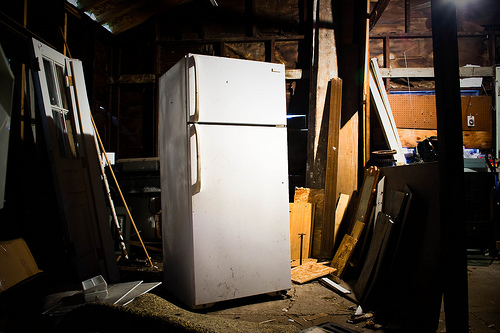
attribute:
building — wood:
[95, 13, 162, 169]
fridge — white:
[148, 40, 297, 309]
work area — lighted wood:
[290, 5, 499, 330]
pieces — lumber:
[297, 54, 389, 268]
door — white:
[30, 34, 133, 274]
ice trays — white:
[77, 268, 113, 306]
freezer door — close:
[184, 52, 287, 124]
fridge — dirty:
[154, 49, 295, 304]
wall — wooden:
[364, 3, 499, 71]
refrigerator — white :
[153, 39, 333, 322]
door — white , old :
[28, 24, 142, 265]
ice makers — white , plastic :
[70, 268, 115, 313]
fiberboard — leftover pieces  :
[275, 208, 382, 297]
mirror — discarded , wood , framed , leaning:
[333, 160, 385, 289]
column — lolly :
[421, 11, 471, 329]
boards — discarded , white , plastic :
[59, 266, 168, 320]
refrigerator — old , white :
[137, 37, 322, 331]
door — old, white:
[24, 36, 126, 273]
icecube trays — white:
[77, 273, 108, 292]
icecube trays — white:
[83, 291, 112, 302]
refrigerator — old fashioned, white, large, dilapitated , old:
[151, 49, 297, 310]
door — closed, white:
[179, 120, 296, 303]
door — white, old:
[180, 50, 288, 126]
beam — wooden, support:
[425, 2, 476, 325]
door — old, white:
[20, 32, 123, 280]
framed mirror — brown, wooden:
[351, 164, 382, 223]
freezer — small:
[152, 52, 290, 133]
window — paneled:
[41, 55, 86, 138]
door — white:
[23, 32, 132, 289]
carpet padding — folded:
[95, 288, 295, 330]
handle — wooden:
[87, 106, 153, 265]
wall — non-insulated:
[216, 4, 498, 67]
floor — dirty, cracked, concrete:
[209, 287, 377, 329]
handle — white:
[166, 46, 220, 226]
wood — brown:
[103, 70, 142, 158]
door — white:
[35, 53, 125, 274]